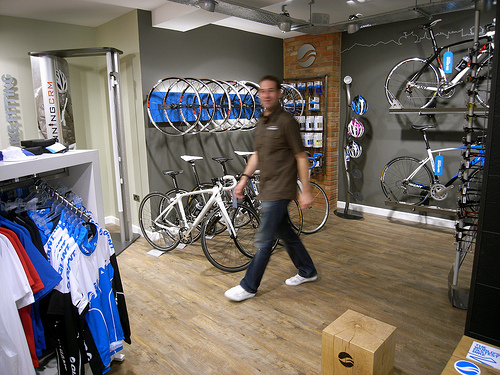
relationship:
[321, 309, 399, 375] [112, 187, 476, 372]
block sitting on floor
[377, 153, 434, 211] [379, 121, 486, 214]
tire on bike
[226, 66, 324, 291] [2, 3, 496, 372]
man walking in room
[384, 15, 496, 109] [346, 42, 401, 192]
bicycle on wall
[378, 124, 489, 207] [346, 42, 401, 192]
bicycle on wall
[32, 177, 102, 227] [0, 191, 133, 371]
rack holding clothing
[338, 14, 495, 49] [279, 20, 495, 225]
design on wall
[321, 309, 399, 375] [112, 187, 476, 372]
block on floor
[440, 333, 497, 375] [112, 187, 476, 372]
box on floor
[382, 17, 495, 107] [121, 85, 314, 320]
bike on rack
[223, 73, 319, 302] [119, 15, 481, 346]
man in store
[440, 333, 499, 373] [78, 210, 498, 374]
box on floor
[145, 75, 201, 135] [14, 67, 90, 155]
tire up on a rack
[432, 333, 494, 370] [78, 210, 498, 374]
package on floor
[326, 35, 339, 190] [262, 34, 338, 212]
brick wall in corner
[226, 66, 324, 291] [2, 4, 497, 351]
man walking in store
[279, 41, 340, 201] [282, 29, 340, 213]
metal logo on wall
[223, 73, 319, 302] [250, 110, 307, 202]
man wearing brown shirt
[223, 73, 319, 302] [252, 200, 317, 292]
man wearing jeans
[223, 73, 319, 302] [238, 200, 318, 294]
man wearing jeans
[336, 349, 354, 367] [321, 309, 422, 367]
logo on block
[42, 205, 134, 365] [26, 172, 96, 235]
blue/white bikesuits on rack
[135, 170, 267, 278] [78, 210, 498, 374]
bicycle on floor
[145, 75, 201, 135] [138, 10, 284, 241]
tire on wall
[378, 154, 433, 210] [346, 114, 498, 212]
tire on bike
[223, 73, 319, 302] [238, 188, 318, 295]
man wearing jeans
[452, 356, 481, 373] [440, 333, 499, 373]
sticker on box